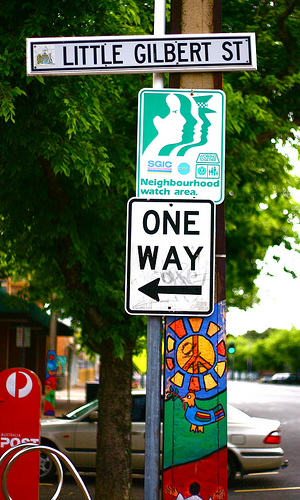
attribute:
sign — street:
[0, 366, 42, 498]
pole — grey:
[140, 314, 166, 496]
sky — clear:
[227, 134, 299, 341]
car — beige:
[47, 377, 275, 484]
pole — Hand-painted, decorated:
[162, 315, 231, 498]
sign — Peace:
[175, 334, 215, 373]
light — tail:
[261, 424, 287, 459]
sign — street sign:
[18, 23, 270, 85]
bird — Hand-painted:
[179, 387, 227, 435]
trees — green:
[2, 0, 177, 206]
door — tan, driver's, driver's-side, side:
[73, 422, 162, 469]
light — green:
[222, 343, 249, 371]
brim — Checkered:
[195, 96, 210, 110]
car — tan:
[40, 383, 292, 486]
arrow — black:
[134, 278, 201, 302]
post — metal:
[142, 315, 163, 499]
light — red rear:
[267, 430, 282, 442]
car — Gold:
[38, 391, 287, 481]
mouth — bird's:
[179, 396, 187, 402]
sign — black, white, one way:
[125, 197, 215, 315]